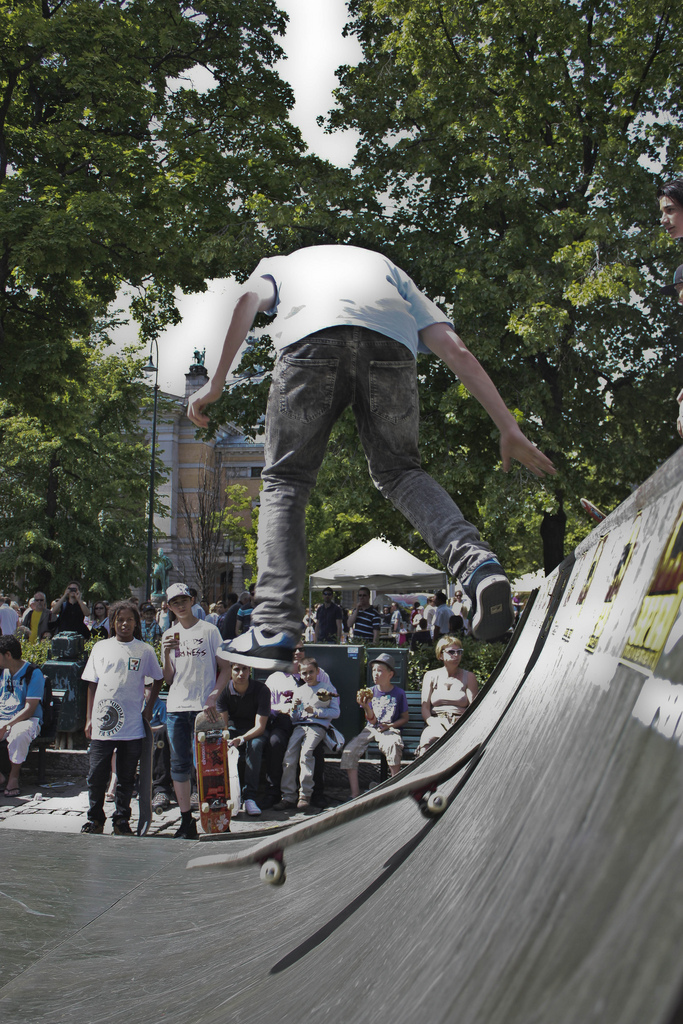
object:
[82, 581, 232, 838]
people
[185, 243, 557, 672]
man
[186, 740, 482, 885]
board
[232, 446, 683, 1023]
ramp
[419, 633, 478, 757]
woman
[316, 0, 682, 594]
tree